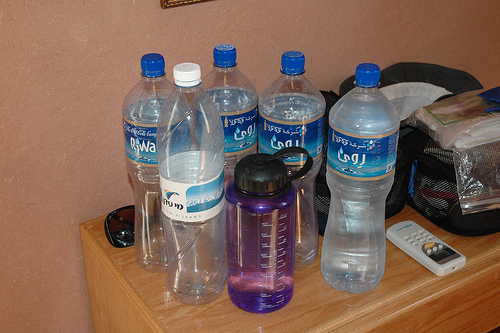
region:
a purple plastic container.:
[202, 151, 319, 311]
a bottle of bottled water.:
[316, 59, 406, 293]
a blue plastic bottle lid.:
[350, 43, 385, 90]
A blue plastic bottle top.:
[276, 40, 313, 80]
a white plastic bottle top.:
[167, 55, 209, 93]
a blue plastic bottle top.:
[132, 46, 169, 83]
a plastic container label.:
[146, 146, 224, 229]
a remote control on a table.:
[381, 212, 474, 282]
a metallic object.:
[386, 52, 498, 234]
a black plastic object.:
[96, 199, 161, 251]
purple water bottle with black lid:
[219, 148, 304, 317]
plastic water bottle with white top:
[164, 60, 234, 322]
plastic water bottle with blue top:
[328, 60, 404, 302]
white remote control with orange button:
[384, 209, 469, 295]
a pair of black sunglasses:
[91, 195, 152, 257]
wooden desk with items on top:
[79, 198, 498, 329]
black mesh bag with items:
[408, 123, 493, 248]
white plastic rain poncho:
[410, 92, 495, 164]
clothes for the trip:
[328, 54, 497, 256]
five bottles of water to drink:
[113, 63, 411, 318]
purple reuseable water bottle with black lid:
[211, 135, 315, 327]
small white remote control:
[391, 209, 476, 331]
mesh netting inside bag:
[408, 143, 498, 253]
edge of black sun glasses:
[101, 200, 156, 254]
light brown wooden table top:
[127, 260, 493, 326]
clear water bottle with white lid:
[162, 60, 231, 326]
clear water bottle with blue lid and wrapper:
[331, 42, 386, 329]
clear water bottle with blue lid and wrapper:
[210, 35, 325, 185]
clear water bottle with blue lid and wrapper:
[116, 45, 176, 185]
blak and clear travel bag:
[375, 49, 498, 239]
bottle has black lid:
[225, 146, 294, 211]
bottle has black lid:
[217, 140, 304, 315]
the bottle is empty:
[160, 62, 228, 313]